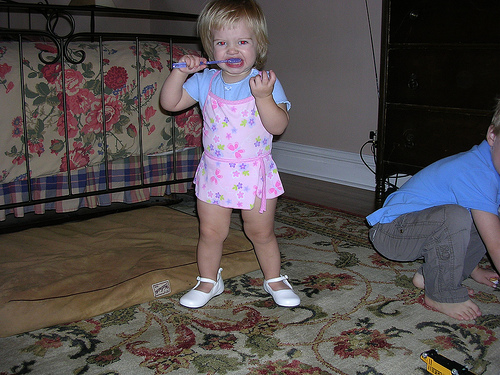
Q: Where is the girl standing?
A: On a rug.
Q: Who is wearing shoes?
A: The little girl.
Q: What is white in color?
A: The shoes.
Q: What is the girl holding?
A: A toothbrush.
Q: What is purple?
A: The toothbrush.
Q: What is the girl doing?
A: Brushing her teeth.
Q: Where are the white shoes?
A: On the girl's feet.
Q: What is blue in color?
A: The children's shirts.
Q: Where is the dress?
A: On the girl.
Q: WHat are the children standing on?
A: A rug.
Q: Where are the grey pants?
A: On the child.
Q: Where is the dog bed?
A: Next to the girl.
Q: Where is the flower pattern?
A: On the rug and the blanket.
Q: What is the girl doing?
A: Brushing her teeth.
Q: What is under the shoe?
A: A rug.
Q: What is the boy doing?
A: Squatting down.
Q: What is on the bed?
A: A bed spread.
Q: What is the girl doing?
A: Brushing her teeth.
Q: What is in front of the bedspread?
A: A metal rail.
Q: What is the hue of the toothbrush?
A: Purple.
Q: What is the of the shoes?
A: White.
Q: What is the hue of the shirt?
A: Blue.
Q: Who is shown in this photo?
A: Children.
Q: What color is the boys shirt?
A: Blue.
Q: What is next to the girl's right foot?
A: Dog bed.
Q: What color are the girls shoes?
A: White.